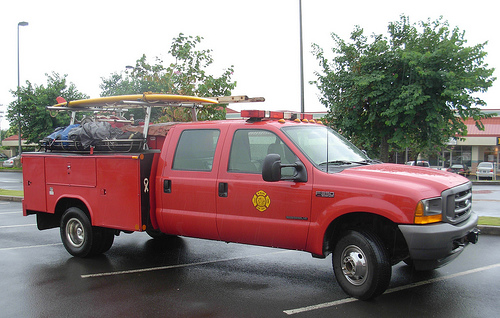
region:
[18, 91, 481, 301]
red work pick up truck with equipment in the bed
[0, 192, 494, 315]
wet pavement of a parking lot with a red truck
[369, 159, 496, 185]
three vehicles parked in the background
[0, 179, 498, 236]
green grass strip between street and parking lot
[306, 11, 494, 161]
green small tree in a small grassy strip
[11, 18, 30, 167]
metal light pole near a parking lot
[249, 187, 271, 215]
yellow insignia on the side door of the red pick up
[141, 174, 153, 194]
white ribbon on the tool storage portion of the truck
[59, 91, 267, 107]
ladder on the rack of a red pick up truck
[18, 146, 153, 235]
tool and equipment storage areas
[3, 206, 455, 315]
the pavement under the truck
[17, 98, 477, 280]
a red truck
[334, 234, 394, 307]
the tire on the truck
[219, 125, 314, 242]
the door on the truck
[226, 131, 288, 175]
the window on the truck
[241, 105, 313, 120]
lights on the top of the truck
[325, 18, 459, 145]
a tree behind the truck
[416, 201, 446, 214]
a headlight on the truck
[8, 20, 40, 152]
a street post behind the truck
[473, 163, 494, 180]
a car parked in front of a building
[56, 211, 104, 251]
the rubber tire of a red truck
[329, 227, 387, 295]
the rubber tire of a red truck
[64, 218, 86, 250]
the silver hubcap of the tire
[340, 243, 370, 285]
the silver hubcap of the tire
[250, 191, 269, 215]
the yellow logo on the truck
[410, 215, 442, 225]
the orange light on the truck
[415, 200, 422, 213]
the orange light on the truck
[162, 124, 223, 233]
the red door on the truck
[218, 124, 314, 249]
the red door on the truck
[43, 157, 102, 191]
the red door on the truck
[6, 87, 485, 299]
a big red truck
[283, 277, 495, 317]
a white line on the road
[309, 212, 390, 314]
a right front tire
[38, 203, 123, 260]
the back right tire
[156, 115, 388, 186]
glass window in the truck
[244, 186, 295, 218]
a yellow sign on the truck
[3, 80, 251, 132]
a yellow thing in the truck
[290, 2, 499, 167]
the green tree in the lot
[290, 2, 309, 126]
a tall pole in the lot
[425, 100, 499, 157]
a red metal roof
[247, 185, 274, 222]
The yellow emblem on the truck.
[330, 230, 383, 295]
The front right tire.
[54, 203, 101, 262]
The back right tire.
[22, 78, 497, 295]
The red trunk on the road.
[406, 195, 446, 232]
The right front light on the truck.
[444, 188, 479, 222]
The grill on the truck.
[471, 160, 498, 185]
The white car that is parked.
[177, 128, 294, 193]
The side windows on the truck.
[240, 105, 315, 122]
Red and white light.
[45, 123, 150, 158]
Cargo on the back of the truck.